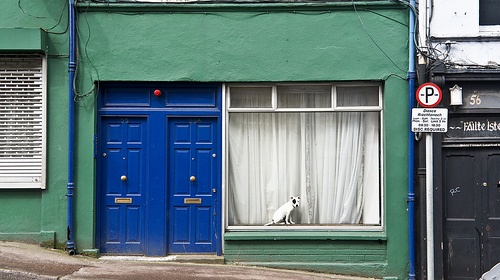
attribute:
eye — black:
[291, 197, 297, 204]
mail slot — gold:
[112, 196, 132, 205]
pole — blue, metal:
[63, 0, 78, 255]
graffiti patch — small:
[448, 184, 462, 196]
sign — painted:
[446, 118, 485, 138]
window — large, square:
[223, 83, 382, 230]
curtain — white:
[228, 86, 308, 226]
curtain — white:
[309, 87, 366, 224]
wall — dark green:
[1, 1, 414, 277]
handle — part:
[360, 150, 374, 172]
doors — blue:
[100, 104, 215, 254]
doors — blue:
[109, 83, 219, 246]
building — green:
[44, 20, 405, 271]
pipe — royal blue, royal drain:
[50, 5, 84, 250]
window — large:
[220, 117, 381, 234]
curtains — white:
[241, 128, 361, 215]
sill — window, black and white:
[233, 221, 388, 241]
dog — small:
[262, 188, 304, 221]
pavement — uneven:
[90, 247, 295, 273]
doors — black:
[430, 90, 494, 277]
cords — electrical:
[410, 39, 448, 83]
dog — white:
[273, 193, 307, 226]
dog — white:
[260, 191, 314, 229]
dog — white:
[261, 189, 311, 219]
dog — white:
[261, 193, 308, 223]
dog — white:
[260, 186, 308, 231]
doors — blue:
[100, 114, 220, 255]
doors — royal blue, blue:
[95, 87, 222, 259]